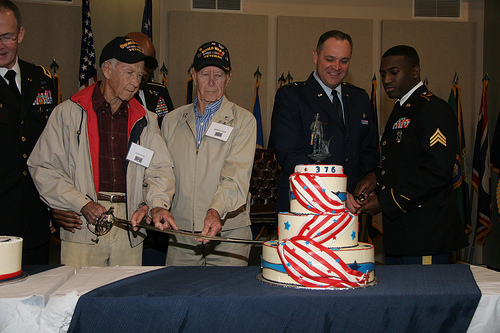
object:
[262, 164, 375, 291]
cake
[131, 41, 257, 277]
man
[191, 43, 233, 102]
head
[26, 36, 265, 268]
men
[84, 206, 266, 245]
sword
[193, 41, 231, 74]
cap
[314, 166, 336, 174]
number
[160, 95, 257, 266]
uniform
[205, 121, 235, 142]
badge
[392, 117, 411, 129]
medals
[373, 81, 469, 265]
uniform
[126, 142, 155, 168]
tag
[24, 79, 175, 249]
jacket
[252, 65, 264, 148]
pole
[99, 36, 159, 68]
hat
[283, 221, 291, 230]
star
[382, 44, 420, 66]
hair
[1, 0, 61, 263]
man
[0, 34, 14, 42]
glasses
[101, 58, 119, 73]
hair